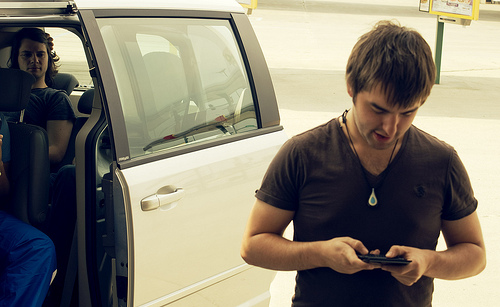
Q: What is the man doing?
A: Pressing buttons on a cell phone.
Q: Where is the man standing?
A: Next to open door of van.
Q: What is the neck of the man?
A: Necklace.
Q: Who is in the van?
A: A young man.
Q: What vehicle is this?
A: A van.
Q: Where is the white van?
A: Behind the man with a necklace.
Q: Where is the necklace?
A: Around the young man's neck.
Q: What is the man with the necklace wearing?
A: A brown t-shirt.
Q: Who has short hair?
A: The man standing next to the van.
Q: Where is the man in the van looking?
A: Into the camera.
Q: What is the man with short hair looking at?
A: Cell phone.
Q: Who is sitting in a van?
A: A young man.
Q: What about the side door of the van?
A: Side door of the van opened.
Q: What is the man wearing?
A: A necklace.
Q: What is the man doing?
A: Texting on a phone.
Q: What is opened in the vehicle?
A: Car door.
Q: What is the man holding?
A: A cellphone.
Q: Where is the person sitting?
A: Back of the van.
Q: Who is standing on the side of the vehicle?
A: A man.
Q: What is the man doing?
A: Using cell phone.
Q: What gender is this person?
A: Male.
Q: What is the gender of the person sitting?
A: Male.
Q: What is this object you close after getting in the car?
A: Door.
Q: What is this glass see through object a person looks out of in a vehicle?
A: Window.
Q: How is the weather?
A: Foggy.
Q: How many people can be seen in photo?
A: 3.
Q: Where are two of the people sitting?
A: In a SUV.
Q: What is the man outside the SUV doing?
A: Dialing cell phone.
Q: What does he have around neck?
A: A necklace.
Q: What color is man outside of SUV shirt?
A: Brown.